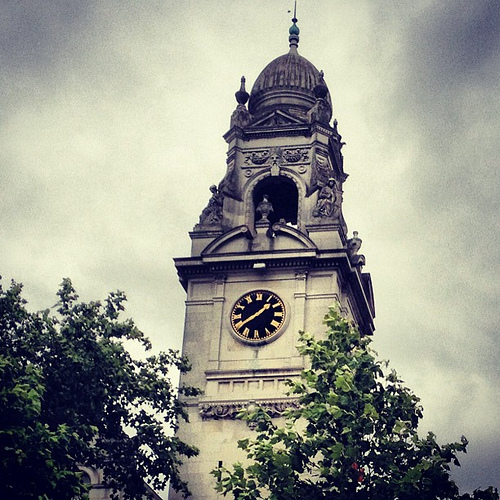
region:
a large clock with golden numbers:
[216, 281, 301, 348]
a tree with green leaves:
[229, 306, 457, 497]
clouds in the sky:
[2, 13, 199, 213]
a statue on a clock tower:
[255, 188, 275, 228]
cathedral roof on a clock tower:
[227, 0, 346, 137]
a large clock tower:
[182, 14, 363, 420]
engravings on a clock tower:
[237, 148, 315, 167]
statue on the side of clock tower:
[182, 174, 232, 229]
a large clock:
[199, 288, 314, 353]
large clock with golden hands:
[214, 287, 316, 357]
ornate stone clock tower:
[136, 8, 434, 489]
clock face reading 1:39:
[223, 287, 300, 351]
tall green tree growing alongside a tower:
[9, 288, 191, 480]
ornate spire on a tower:
[268, 3, 315, 54]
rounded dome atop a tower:
[208, 7, 389, 137]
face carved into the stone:
[230, 144, 327, 170]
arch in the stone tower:
[234, 168, 319, 234]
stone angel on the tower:
[189, 178, 230, 239]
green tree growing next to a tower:
[291, 311, 409, 477]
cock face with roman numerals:
[222, 281, 300, 356]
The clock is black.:
[206, 262, 291, 357]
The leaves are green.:
[227, 301, 424, 482]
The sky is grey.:
[26, 55, 472, 348]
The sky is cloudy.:
[18, 25, 498, 340]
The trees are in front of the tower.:
[4, 259, 439, 481]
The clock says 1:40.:
[215, 278, 298, 360]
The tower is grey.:
[161, 117, 374, 495]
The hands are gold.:
[225, 278, 291, 354]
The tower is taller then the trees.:
[81, 2, 446, 490]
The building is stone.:
[189, 79, 346, 493]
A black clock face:
[220, 275, 293, 352]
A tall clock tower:
[167, 71, 349, 406]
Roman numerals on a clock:
[220, 280, 281, 350]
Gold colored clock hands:
[222, 282, 277, 347]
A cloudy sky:
[5, 29, 235, 223]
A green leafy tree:
[5, 279, 184, 470]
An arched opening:
[238, 151, 311, 251]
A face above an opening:
[262, 144, 284, 177]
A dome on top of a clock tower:
[241, 41, 342, 113]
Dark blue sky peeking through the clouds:
[417, 2, 487, 59]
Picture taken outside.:
[39, 187, 465, 458]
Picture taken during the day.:
[57, 174, 482, 433]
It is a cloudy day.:
[47, 172, 205, 306]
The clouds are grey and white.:
[49, 186, 163, 261]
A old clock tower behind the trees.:
[187, 234, 386, 482]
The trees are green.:
[37, 330, 412, 497]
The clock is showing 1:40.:
[197, 276, 314, 398]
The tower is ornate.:
[194, 179, 379, 251]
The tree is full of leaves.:
[10, 287, 415, 479]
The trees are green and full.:
[36, 311, 474, 491]